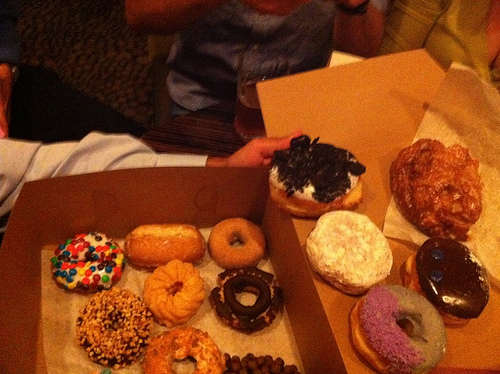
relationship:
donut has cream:
[403, 236, 495, 331] [404, 232, 489, 322]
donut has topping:
[269, 132, 365, 215] [272, 132, 364, 200]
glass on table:
[236, 42, 289, 144] [149, 107, 252, 151]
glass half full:
[236, 42, 289, 144] [236, 85, 267, 131]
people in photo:
[1, 1, 338, 209] [4, 7, 496, 365]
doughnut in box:
[144, 257, 208, 323] [5, 169, 344, 367]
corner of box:
[381, 43, 499, 161] [1, 47, 494, 369]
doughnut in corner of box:
[390, 135, 485, 235] [5, 169, 344, 367]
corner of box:
[381, 43, 499, 161] [5, 169, 344, 367]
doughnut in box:
[77, 287, 149, 367] [5, 169, 344, 367]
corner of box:
[2, 175, 118, 292] [1, 47, 494, 369]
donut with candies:
[51, 229, 123, 292] [52, 231, 122, 290]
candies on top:
[52, 231, 122, 290] [50, 232, 123, 289]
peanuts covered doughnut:
[77, 287, 148, 366] [77, 287, 149, 367]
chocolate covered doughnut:
[212, 267, 282, 335] [215, 263, 281, 334]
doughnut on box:
[269, 132, 365, 215] [1, 47, 494, 369]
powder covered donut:
[305, 209, 392, 289] [306, 208, 395, 292]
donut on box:
[306, 208, 395, 292] [1, 47, 494, 369]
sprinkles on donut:
[358, 283, 421, 366] [350, 284, 448, 372]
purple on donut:
[363, 284, 444, 371] [350, 284, 448, 372]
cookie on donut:
[146, 325, 219, 372] [148, 325, 223, 373]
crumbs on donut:
[272, 132, 364, 200] [269, 132, 365, 215]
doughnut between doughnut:
[125, 221, 207, 266] [51, 229, 123, 292]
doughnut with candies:
[51, 229, 123, 292] [52, 231, 122, 290]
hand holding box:
[206, 133, 292, 165] [1, 47, 494, 369]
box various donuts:
[1, 47, 494, 369] [50, 132, 489, 371]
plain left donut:
[211, 214, 265, 268] [207, 215, 267, 270]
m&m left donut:
[52, 231, 122, 290] [51, 229, 123, 292]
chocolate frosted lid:
[425, 239, 489, 317] [256, 34, 499, 374]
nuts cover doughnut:
[77, 287, 148, 366] [77, 287, 149, 367]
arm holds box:
[1, 153, 220, 206] [1, 47, 494, 369]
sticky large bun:
[392, 138, 482, 236] [390, 135, 485, 235]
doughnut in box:
[125, 221, 207, 266] [5, 169, 344, 367]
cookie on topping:
[272, 132, 364, 200] [272, 132, 364, 200]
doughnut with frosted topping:
[269, 132, 365, 215] [272, 132, 364, 200]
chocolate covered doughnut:
[76, 290, 149, 367] [77, 287, 149, 367]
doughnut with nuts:
[77, 287, 149, 367] [77, 287, 148, 366]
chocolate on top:
[76, 290, 149, 367] [78, 286, 147, 364]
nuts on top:
[77, 287, 148, 366] [78, 286, 147, 364]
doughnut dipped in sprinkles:
[350, 284, 448, 372] [358, 283, 421, 366]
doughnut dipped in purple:
[350, 284, 448, 372] [363, 284, 444, 371]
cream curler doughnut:
[55, 232, 124, 286] [51, 229, 123, 292]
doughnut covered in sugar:
[306, 208, 395, 292] [305, 209, 392, 289]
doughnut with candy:
[51, 229, 123, 292] [52, 231, 122, 290]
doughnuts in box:
[50, 132, 489, 371] [1, 47, 494, 369]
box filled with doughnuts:
[1, 47, 494, 369] [50, 132, 489, 371]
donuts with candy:
[51, 229, 123, 292] [52, 231, 122, 290]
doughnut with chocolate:
[215, 263, 281, 334] [212, 267, 282, 335]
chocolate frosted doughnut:
[425, 239, 489, 317] [403, 236, 495, 331]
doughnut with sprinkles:
[350, 284, 448, 372] [358, 283, 421, 366]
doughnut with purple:
[350, 284, 448, 372] [363, 284, 444, 371]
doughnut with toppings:
[269, 132, 365, 215] [272, 132, 364, 200]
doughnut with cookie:
[269, 132, 365, 215] [273, 132, 364, 207]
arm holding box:
[1, 153, 220, 206] [1, 47, 494, 369]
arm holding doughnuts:
[1, 153, 220, 206] [50, 132, 489, 371]